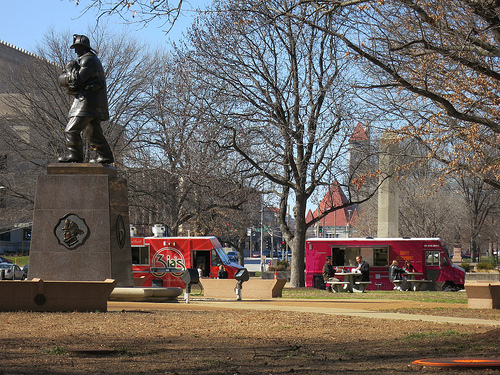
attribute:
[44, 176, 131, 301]
base — concrete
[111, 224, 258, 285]
truck — food truck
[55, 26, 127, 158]
fireman — large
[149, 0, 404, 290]
leafless tree — large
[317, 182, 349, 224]
roof — pointed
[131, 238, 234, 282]
truck — parked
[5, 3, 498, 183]
sky — blue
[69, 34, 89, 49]
helmet — firefighter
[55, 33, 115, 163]
statue — fireman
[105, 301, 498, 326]
sidewalk — concrete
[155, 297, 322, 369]
grass — brown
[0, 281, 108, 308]
bench — concrete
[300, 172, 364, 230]
roof — red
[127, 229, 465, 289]
trucks — red